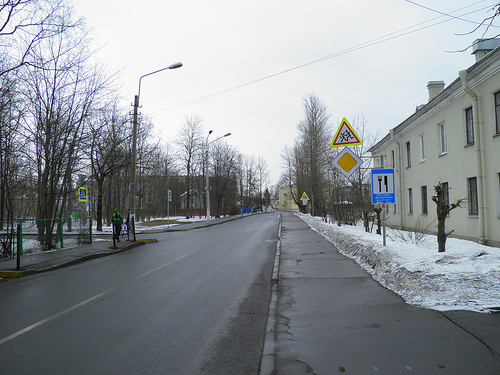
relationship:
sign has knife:
[371, 169, 396, 206] [385, 176, 389, 193]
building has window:
[369, 36, 499, 247] [465, 105, 476, 148]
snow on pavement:
[294, 209, 500, 313] [261, 211, 500, 375]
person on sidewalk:
[111, 208, 123, 248] [1, 236, 157, 278]